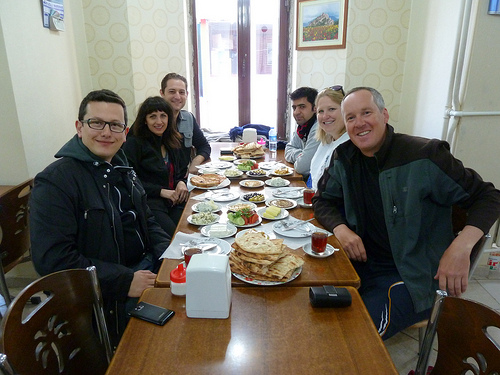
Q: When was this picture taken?
A: Daytime.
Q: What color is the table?
A: Brown.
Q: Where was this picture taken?
A: Kitchen.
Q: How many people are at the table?
A: 6.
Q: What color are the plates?
A: White.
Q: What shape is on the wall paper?
A: Circle.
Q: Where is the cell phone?
A: On table.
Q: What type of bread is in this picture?
A: Pita.